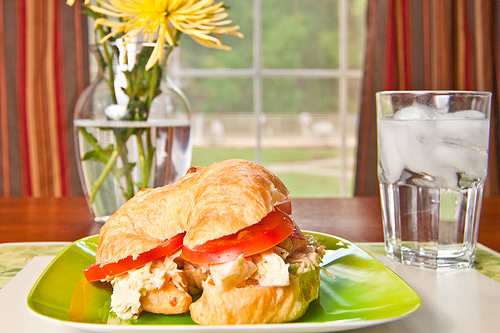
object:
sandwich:
[103, 175, 314, 314]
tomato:
[185, 211, 303, 261]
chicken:
[113, 267, 174, 317]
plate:
[25, 230, 423, 332]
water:
[388, 186, 481, 249]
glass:
[371, 78, 483, 265]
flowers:
[94, 1, 235, 54]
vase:
[66, 50, 197, 212]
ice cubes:
[385, 109, 479, 182]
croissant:
[118, 171, 261, 237]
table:
[2, 189, 472, 332]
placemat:
[1, 239, 499, 329]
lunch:
[83, 158, 327, 326]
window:
[111, 1, 366, 190]